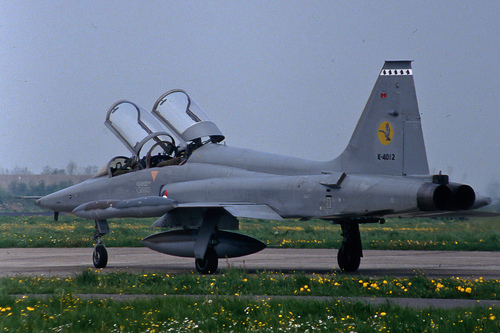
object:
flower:
[381, 279, 388, 284]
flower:
[464, 286, 473, 294]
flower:
[487, 315, 496, 320]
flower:
[304, 283, 310, 289]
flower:
[26, 307, 33, 310]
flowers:
[303, 283, 310, 289]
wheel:
[91, 244, 112, 269]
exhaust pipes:
[413, 181, 456, 215]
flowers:
[293, 289, 299, 296]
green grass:
[0, 267, 500, 298]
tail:
[333, 58, 433, 177]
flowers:
[269, 277, 273, 281]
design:
[379, 67, 416, 78]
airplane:
[35, 58, 495, 273]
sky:
[1, 1, 500, 176]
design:
[374, 118, 398, 147]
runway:
[0, 244, 500, 282]